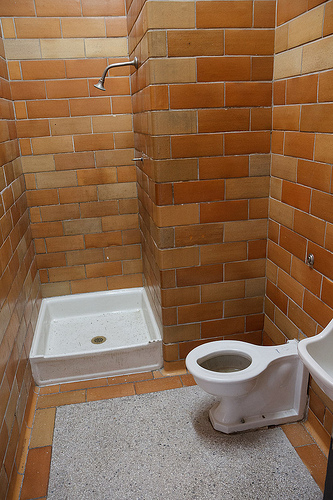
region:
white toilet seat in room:
[178, 334, 315, 431]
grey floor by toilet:
[51, 384, 291, 499]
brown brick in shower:
[0, 4, 146, 292]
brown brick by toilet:
[151, 7, 329, 353]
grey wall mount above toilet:
[303, 253, 317, 262]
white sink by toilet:
[295, 326, 331, 400]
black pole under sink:
[318, 441, 331, 497]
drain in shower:
[87, 333, 104, 344]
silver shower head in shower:
[91, 56, 146, 92]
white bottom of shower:
[30, 296, 163, 384]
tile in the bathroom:
[192, 54, 251, 81]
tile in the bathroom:
[225, 265, 264, 280]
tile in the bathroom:
[229, 134, 271, 151]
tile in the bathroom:
[158, 247, 199, 266]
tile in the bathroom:
[51, 118, 90, 136]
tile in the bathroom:
[76, 137, 109, 152]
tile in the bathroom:
[72, 98, 111, 112]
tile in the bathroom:
[274, 277, 304, 304]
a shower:
[45, 294, 149, 364]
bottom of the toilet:
[213, 404, 249, 434]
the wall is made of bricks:
[162, 202, 262, 336]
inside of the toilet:
[213, 358, 236, 372]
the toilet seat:
[207, 371, 228, 383]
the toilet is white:
[187, 342, 307, 427]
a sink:
[302, 338, 331, 361]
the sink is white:
[299, 336, 328, 366]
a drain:
[91, 334, 107, 343]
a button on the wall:
[304, 253, 316, 266]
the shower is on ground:
[27, 261, 179, 371]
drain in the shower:
[83, 329, 118, 360]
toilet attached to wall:
[179, 318, 316, 422]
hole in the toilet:
[176, 333, 259, 386]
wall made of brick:
[6, 24, 314, 265]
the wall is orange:
[35, 55, 312, 253]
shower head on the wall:
[88, 48, 163, 106]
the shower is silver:
[90, 49, 207, 115]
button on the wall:
[296, 233, 332, 281]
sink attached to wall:
[294, 310, 332, 397]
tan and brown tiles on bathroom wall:
[10, 13, 64, 52]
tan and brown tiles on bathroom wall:
[29, 89, 74, 146]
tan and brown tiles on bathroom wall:
[64, 164, 126, 205]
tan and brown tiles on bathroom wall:
[71, 223, 113, 254]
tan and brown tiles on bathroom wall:
[163, 203, 200, 230]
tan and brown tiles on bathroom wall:
[223, 215, 261, 262]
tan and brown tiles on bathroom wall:
[161, 79, 231, 137]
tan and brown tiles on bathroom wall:
[174, 280, 207, 308]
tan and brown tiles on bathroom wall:
[281, 180, 319, 212]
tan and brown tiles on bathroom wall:
[282, 98, 329, 136]